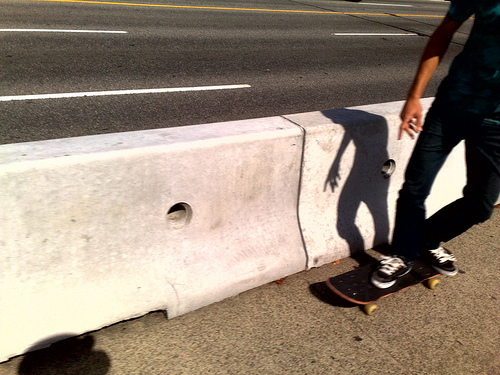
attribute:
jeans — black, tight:
[389, 91, 499, 258]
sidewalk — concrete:
[213, 287, 444, 374]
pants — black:
[385, 109, 499, 254]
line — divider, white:
[332, 27, 419, 42]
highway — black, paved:
[8, 4, 413, 108]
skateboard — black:
[321, 217, 398, 334]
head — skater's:
[314, 98, 369, 124]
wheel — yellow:
[363, 300, 379, 317]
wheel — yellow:
[427, 276, 442, 291]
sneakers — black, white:
[321, 204, 456, 294]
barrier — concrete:
[12, 76, 491, 353]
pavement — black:
[51, 4, 308, 106]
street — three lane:
[0, 0, 474, 146]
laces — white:
[383, 257, 395, 275]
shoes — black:
[335, 216, 435, 325]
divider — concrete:
[1, 90, 499, 370]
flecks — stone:
[325, 333, 391, 362]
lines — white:
[1, 0, 484, 149]